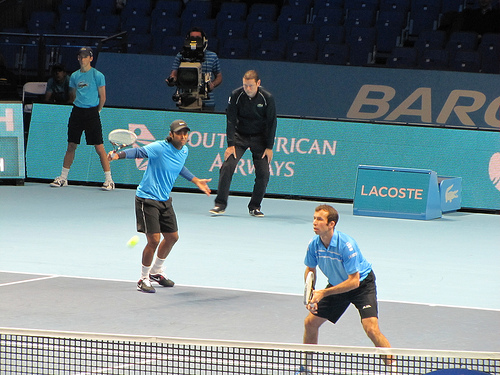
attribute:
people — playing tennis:
[104, 117, 400, 374]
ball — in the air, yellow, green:
[125, 234, 139, 251]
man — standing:
[104, 118, 213, 292]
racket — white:
[108, 123, 137, 156]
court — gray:
[1, 180, 500, 370]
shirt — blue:
[121, 135, 196, 203]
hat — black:
[168, 117, 194, 137]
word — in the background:
[347, 78, 500, 128]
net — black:
[3, 327, 500, 372]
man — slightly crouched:
[209, 69, 281, 219]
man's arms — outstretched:
[102, 144, 213, 203]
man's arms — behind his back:
[67, 69, 106, 112]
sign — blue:
[26, 103, 500, 212]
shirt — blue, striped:
[302, 233, 373, 287]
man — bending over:
[290, 202, 405, 374]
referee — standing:
[52, 45, 115, 195]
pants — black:
[217, 146, 273, 211]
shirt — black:
[223, 84, 279, 151]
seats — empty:
[3, 1, 500, 77]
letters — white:
[357, 182, 424, 206]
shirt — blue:
[172, 47, 222, 107]